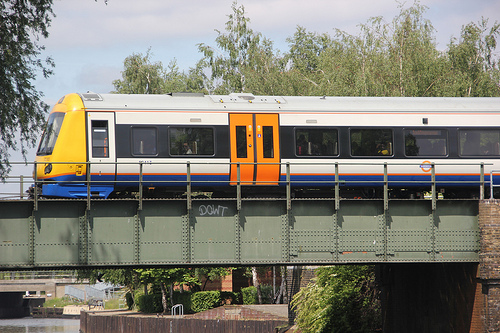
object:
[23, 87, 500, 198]
train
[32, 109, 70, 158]
windshield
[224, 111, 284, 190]
door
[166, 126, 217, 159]
passenger window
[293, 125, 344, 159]
passenger window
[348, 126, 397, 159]
passenger window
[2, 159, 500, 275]
bridge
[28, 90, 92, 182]
train front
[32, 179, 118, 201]
bumper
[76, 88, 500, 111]
roof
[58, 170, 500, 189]
lower train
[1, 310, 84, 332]
water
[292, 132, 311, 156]
people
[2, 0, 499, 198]
sky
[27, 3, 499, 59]
clouds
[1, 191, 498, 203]
tracks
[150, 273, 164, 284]
leaves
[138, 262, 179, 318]
tree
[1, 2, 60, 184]
tree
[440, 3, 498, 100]
tree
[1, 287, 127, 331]
canal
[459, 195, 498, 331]
brick base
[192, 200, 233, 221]
graffiti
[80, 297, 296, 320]
dock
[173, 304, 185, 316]
rails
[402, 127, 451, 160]
passenger window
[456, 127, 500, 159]
passenger window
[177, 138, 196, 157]
passenger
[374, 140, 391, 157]
passenger